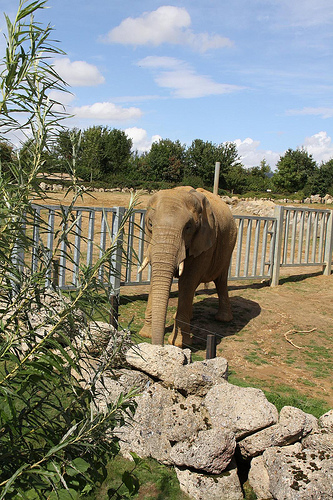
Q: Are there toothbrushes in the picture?
A: No, there are no toothbrushes.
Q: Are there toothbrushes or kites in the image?
A: No, there are no toothbrushes or kites.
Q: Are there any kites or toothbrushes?
A: No, there are no toothbrushes or kites.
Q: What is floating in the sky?
A: The clouds are floating in the sky.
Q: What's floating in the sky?
A: The clouds are floating in the sky.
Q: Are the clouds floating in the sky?
A: Yes, the clouds are floating in the sky.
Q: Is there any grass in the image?
A: Yes, there is grass.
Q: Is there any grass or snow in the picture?
A: Yes, there is grass.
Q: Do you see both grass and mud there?
A: No, there is grass but no mud.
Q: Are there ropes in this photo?
A: No, there are no ropes.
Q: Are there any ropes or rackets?
A: No, there are no ropes or rackets.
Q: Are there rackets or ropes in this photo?
A: No, there are no ropes or rackets.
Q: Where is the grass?
A: The grass is on the ground.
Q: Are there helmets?
A: No, there are no helmets.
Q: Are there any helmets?
A: No, there are no helmets.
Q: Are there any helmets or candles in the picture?
A: No, there are no helmets or candles.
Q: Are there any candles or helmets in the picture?
A: No, there are no helmets or candles.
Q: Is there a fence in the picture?
A: Yes, there is a fence.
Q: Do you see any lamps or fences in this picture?
A: Yes, there is a fence.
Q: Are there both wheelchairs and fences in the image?
A: No, there is a fence but no wheelchairs.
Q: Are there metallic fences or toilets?
A: Yes, there is a metal fence.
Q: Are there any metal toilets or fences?
A: Yes, there is a metal fence.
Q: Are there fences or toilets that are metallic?
A: Yes, the fence is metallic.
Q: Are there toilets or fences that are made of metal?
A: Yes, the fence is made of metal.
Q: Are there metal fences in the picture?
A: Yes, there is a metal fence.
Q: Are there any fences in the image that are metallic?
A: Yes, there is a metal fence.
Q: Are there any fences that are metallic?
A: Yes, there is a fence that is metallic.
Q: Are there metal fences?
A: Yes, there is a fence that is made of metal.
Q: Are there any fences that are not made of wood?
A: Yes, there is a fence that is made of metal.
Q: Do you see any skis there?
A: No, there are no skis.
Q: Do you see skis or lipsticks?
A: No, there are no skis or lipsticks.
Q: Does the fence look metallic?
A: Yes, the fence is metallic.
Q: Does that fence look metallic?
A: Yes, the fence is metallic.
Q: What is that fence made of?
A: The fence is made of metal.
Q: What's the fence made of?
A: The fence is made of metal.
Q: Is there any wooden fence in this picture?
A: No, there is a fence but it is metallic.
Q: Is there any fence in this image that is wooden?
A: No, there is a fence but it is metallic.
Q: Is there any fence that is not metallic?
A: No, there is a fence but it is metallic.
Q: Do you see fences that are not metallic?
A: No, there is a fence but it is metallic.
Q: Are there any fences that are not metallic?
A: No, there is a fence but it is metallic.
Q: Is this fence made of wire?
A: No, the fence is made of metal.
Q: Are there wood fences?
A: No, there is a fence but it is made of metal.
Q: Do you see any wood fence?
A: No, there is a fence but it is made of metal.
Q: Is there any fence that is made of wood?
A: No, there is a fence but it is made of metal.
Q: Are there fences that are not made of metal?
A: No, there is a fence but it is made of metal.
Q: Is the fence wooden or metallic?
A: The fence is metallic.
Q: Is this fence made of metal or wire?
A: The fence is made of metal.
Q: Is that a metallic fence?
A: Yes, that is a metallic fence.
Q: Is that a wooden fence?
A: No, that is a metallic fence.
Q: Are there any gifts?
A: No, there are no gifts.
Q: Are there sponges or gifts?
A: No, there are no gifts or sponges.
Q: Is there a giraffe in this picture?
A: No, there are no giraffes.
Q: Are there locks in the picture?
A: No, there are no locks.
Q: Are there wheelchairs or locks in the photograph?
A: No, there are no locks or wheelchairs.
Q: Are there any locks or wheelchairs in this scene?
A: No, there are no locks or wheelchairs.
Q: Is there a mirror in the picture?
A: No, there are no mirrors.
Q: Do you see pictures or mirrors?
A: No, there are no mirrors or pictures.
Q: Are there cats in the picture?
A: No, there are no cats.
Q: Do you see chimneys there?
A: No, there are no chimneys.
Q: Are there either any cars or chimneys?
A: No, there are no chimneys or cars.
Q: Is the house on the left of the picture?
A: Yes, the house is on the left of the image.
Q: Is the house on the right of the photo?
A: No, the house is on the left of the image.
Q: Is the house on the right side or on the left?
A: The house is on the left of the image.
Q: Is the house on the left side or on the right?
A: The house is on the left of the image.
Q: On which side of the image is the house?
A: The house is on the left of the image.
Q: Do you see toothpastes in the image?
A: No, there are no toothpastes.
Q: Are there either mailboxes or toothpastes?
A: No, there are no toothpastes or mailboxes.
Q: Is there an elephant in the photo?
A: Yes, there is an elephant.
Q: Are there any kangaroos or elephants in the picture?
A: Yes, there is an elephant.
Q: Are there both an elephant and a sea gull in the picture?
A: No, there is an elephant but no seagulls.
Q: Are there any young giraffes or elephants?
A: Yes, there is a young elephant.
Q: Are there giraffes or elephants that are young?
A: Yes, the elephant is young.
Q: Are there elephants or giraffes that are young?
A: Yes, the elephant is young.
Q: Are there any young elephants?
A: Yes, there is a young elephant.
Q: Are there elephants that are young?
A: Yes, there is an elephant that is young.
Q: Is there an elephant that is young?
A: Yes, there is an elephant that is young.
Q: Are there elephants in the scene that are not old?
A: Yes, there is an young elephant.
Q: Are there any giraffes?
A: No, there are no giraffes.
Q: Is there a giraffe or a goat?
A: No, there are no giraffes or goats.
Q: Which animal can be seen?
A: The animal is an elephant.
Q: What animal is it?
A: The animal is an elephant.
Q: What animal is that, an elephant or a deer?
A: This is an elephant.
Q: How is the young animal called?
A: The animal is an elephant.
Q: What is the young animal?
A: The animal is an elephant.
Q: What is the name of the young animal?
A: The animal is an elephant.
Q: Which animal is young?
A: The animal is an elephant.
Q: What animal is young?
A: The animal is an elephant.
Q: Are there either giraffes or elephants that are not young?
A: No, there is an elephant but it is young.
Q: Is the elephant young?
A: Yes, the elephant is young.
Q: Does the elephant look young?
A: Yes, the elephant is young.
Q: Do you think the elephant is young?
A: Yes, the elephant is young.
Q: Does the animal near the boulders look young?
A: Yes, the elephant is young.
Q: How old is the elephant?
A: The elephant is young.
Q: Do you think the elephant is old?
A: No, the elephant is young.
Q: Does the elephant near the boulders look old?
A: No, the elephant is young.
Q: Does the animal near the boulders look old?
A: No, the elephant is young.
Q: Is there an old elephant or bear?
A: No, there is an elephant but it is young.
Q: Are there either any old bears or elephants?
A: No, there is an elephant but it is young.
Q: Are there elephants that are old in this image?
A: No, there is an elephant but it is young.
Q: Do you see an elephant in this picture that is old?
A: No, there is an elephant but it is young.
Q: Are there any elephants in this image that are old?
A: No, there is an elephant but it is young.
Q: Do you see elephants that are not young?
A: No, there is an elephant but it is young.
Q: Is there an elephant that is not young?
A: No, there is an elephant but it is young.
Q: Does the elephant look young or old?
A: The elephant is young.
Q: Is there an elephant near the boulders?
A: Yes, there is an elephant near the boulders.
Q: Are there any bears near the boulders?
A: No, there is an elephant near the boulders.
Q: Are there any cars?
A: No, there are no cars.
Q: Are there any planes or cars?
A: No, there are no cars or planes.